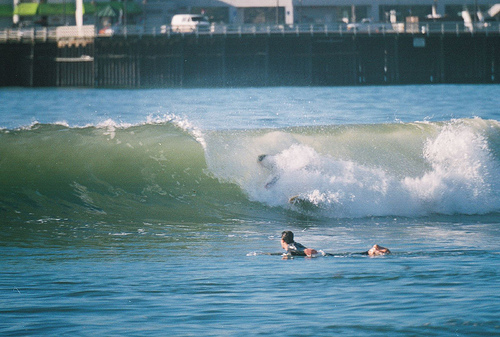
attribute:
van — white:
[168, 4, 226, 39]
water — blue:
[12, 132, 497, 329]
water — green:
[5, 88, 497, 334]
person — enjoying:
[267, 224, 393, 262]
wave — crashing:
[106, 97, 498, 257]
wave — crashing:
[9, 105, 498, 230]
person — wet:
[223, 227, 453, 274]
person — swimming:
[274, 233, 389, 258]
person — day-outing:
[225, 179, 467, 309]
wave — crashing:
[0, 113, 499, 222]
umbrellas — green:
[6, 0, 143, 27]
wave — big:
[0, 116, 497, 239]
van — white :
[169, 9, 214, 34]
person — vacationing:
[276, 222, 392, 262]